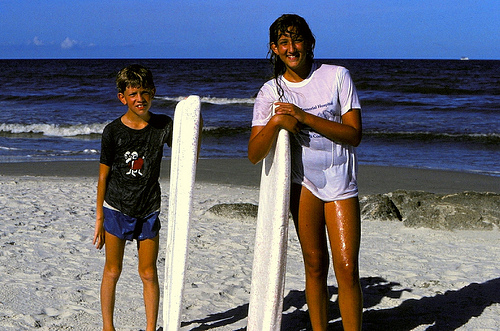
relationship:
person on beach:
[92, 63, 203, 330] [1, 154, 499, 329]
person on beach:
[247, 13, 364, 331] [1, 154, 499, 329]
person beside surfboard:
[92, 63, 203, 330] [160, 93, 202, 329]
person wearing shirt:
[92, 63, 203, 330] [98, 112, 173, 218]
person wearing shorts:
[92, 63, 203, 330] [103, 207, 162, 241]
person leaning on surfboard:
[247, 13, 364, 331] [246, 102, 291, 330]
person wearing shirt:
[247, 13, 364, 331] [250, 62, 362, 201]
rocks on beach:
[372, 221, 475, 260] [1, 154, 499, 329]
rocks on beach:
[209, 201, 260, 217] [1, 154, 499, 329]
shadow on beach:
[323, 273, 500, 329] [1, 154, 499, 329]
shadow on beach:
[156, 276, 412, 330] [1, 154, 499, 329]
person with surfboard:
[92, 63, 203, 330] [160, 93, 202, 329]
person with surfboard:
[247, 13, 364, 331] [246, 102, 291, 330]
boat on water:
[459, 54, 470, 61] [0, 57, 500, 175]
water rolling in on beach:
[0, 57, 500, 175] [1, 154, 499, 329]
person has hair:
[247, 13, 364, 331] [266, 13, 316, 105]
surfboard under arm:
[246, 102, 291, 330] [248, 78, 300, 165]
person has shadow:
[92, 63, 203, 330] [156, 276, 412, 330]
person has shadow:
[247, 13, 364, 331] [323, 273, 500, 329]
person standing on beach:
[247, 13, 364, 331] [1, 154, 499, 329]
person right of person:
[247, 13, 364, 331] [92, 63, 203, 330]